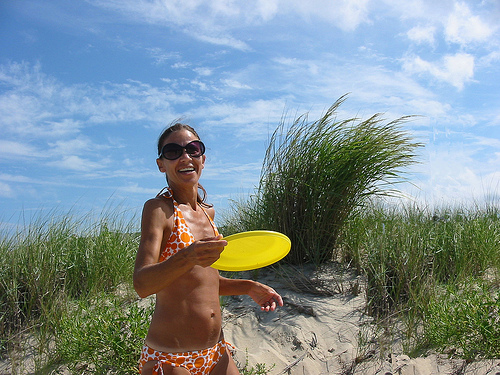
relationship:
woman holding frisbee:
[123, 122, 286, 374] [203, 228, 287, 279]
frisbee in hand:
[203, 228, 287, 279] [190, 236, 230, 273]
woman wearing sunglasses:
[123, 122, 286, 374] [161, 138, 212, 159]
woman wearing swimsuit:
[123, 122, 286, 374] [135, 200, 238, 372]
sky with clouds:
[2, 1, 499, 222] [2, 1, 499, 215]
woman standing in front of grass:
[123, 122, 286, 374] [2, 117, 495, 360]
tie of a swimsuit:
[152, 360, 161, 374] [135, 200, 238, 372]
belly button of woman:
[208, 307, 218, 321] [123, 122, 286, 374]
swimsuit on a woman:
[135, 200, 238, 372] [123, 122, 286, 374]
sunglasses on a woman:
[161, 138, 212, 159] [123, 122, 286, 374]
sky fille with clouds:
[2, 1, 499, 222] [2, 1, 499, 215]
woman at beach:
[123, 122, 286, 374] [4, 1, 500, 373]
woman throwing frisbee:
[123, 122, 286, 374] [203, 228, 287, 279]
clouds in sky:
[2, 1, 499, 215] [2, 1, 499, 222]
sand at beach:
[8, 253, 492, 374] [4, 1, 500, 373]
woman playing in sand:
[123, 122, 286, 374] [8, 253, 492, 374]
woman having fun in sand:
[123, 122, 286, 374] [8, 253, 492, 374]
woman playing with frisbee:
[123, 122, 286, 374] [203, 228, 287, 279]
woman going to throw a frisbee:
[123, 122, 286, 374] [203, 228, 287, 279]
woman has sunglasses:
[123, 122, 286, 374] [161, 138, 212, 159]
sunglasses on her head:
[161, 138, 212, 159] [153, 126, 211, 187]